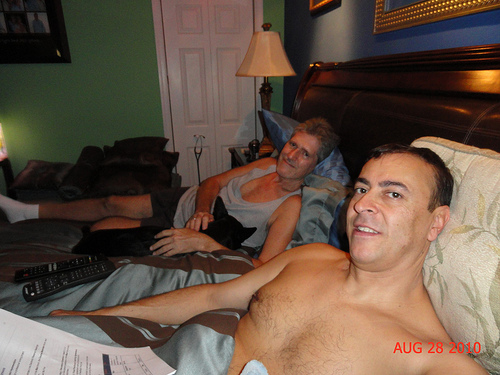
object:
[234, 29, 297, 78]
lamp shade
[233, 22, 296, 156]
lamp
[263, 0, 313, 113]
corner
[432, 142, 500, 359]
pillow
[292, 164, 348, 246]
pillow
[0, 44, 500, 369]
bed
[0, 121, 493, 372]
two people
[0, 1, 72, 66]
frame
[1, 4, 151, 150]
wall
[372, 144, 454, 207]
brown hair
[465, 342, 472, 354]
numbers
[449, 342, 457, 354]
two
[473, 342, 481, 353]
zero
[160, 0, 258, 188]
door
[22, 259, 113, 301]
remote control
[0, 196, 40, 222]
socks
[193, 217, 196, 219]
ring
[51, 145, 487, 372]
man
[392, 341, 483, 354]
timestamp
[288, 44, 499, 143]
bed rest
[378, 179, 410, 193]
thick eyebrows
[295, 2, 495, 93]
wall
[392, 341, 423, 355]
aug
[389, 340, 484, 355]
date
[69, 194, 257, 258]
black dog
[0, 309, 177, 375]
paper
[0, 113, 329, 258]
man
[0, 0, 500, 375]
bedroom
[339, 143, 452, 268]
head